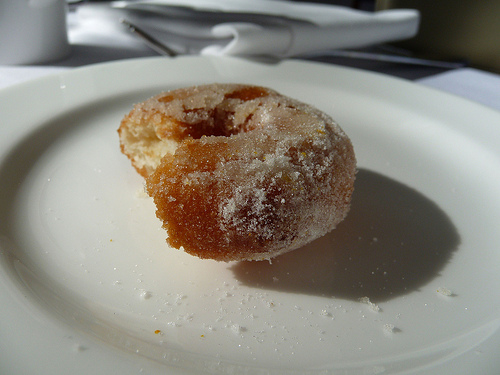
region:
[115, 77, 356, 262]
someone has started eating the donut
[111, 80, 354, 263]
donut has a few bites missing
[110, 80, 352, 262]
donut is covered in sugar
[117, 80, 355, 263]
donut casts shadow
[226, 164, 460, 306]
shadow is cast by donut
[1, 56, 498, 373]
plate holds donut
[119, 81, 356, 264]
donut is a dessert or breakfast item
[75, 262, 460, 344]
sugar sits on plate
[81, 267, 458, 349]
sugar has fallen off of donut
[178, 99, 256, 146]
donut has a hole through the middle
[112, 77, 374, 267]
a sugar donut on a plate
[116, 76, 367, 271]
a sugar donut on a white plate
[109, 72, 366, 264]
a half eaten sugar donut on a plate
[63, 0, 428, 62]
a white napkin near a plate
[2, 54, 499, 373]
a plate with a sugar donut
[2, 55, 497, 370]
a white plate with a sugar donut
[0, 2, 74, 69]
a white cup on a table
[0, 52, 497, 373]
a plate with a sugar crumbs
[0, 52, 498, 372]
a white plate with a sugar crumbs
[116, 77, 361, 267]
an unfinished sugar donut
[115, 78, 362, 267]
this is a piece of a donut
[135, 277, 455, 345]
this is sugar crystals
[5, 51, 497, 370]
this is a white plate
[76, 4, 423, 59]
this is a white napkin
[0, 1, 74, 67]
thats a white mug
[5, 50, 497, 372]
a donut on a plate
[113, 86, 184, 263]
a part of donut eaten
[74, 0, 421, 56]
a napkin on plate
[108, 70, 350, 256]
partially eaten donut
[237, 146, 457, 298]
shadow of the donut on the plate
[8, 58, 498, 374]
white plate on the table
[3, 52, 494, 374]
donut on white plate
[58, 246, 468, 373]
sugar from the donut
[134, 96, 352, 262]
donut covered in powder sugar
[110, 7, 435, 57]
white napkin on the table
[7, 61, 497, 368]
white rim of the plate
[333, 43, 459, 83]
shadow of napkin on the table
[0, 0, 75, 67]
white cup on the table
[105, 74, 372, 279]
a doughnut is on a plate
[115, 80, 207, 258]
the doughnut has a bite taken it out of it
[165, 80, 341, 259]
the doughnut has some sugar as a topping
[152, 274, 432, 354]
some sugar is on the plate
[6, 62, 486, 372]
the plate is white in color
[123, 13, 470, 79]
a fork is next to the plate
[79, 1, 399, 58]
a napkin is next to the plate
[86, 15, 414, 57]
the napkin has been folded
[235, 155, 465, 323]
the doughnuts shadow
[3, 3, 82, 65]
another item is on the table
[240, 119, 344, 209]
sugar on the donut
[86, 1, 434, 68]
white napkin on the table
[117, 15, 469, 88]
silver fork on the table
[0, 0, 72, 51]
coffee mug on the table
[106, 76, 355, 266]
dough nut of the white plate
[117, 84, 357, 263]
small round half eaten doughnut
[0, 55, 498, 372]
large round white plate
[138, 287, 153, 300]
crumb of sugar dust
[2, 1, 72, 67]
small round white cup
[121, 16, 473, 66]
long silver metal fork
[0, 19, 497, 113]
large wide white table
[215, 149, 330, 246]
powdered sugar on dougnut